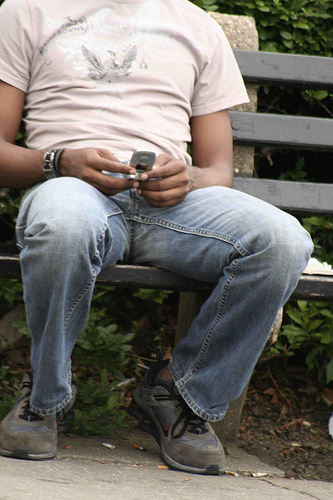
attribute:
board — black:
[1, 241, 330, 299]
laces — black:
[148, 388, 204, 447]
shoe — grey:
[114, 351, 239, 478]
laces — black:
[11, 408, 44, 424]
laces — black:
[155, 387, 222, 446]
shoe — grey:
[118, 350, 233, 476]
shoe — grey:
[0, 366, 232, 475]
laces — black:
[142, 379, 212, 440]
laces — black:
[13, 374, 48, 427]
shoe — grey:
[0, 368, 72, 458]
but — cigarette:
[221, 466, 241, 475]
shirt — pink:
[4, 4, 274, 171]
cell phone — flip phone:
[122, 151, 163, 195]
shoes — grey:
[0, 351, 229, 481]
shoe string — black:
[158, 386, 207, 439]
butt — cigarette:
[100, 434, 172, 472]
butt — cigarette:
[52, 438, 76, 452]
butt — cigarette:
[100, 440, 116, 449]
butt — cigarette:
[98, 440, 122, 450]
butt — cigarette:
[89, 428, 170, 472]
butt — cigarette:
[154, 461, 275, 479]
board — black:
[293, 273, 322, 295]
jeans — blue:
[15, 156, 317, 427]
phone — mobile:
[121, 147, 154, 183]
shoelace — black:
[165, 402, 195, 443]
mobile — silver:
[124, 148, 156, 183]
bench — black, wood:
[253, 50, 331, 114]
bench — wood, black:
[230, 40, 332, 216]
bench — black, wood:
[123, 108, 331, 313]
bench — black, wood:
[248, 37, 332, 99]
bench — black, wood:
[21, 31, 332, 291]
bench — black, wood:
[4, 255, 332, 293]